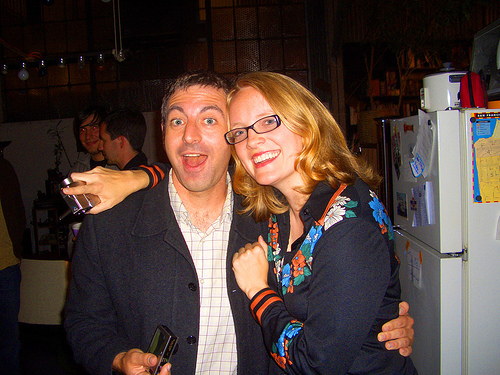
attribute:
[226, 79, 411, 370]
woman — middle age, posing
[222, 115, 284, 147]
glasses — black, on the wall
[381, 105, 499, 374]
fridge — white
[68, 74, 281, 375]
man — posing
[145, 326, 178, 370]
camera — silver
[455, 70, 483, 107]
bag — red, black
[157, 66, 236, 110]
hair — dark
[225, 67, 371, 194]
hair — light colored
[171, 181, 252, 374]
shirt — colorful, white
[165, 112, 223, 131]
eyes — bue, red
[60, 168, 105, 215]
camera — digital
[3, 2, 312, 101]
tiles — brown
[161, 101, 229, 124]
eye brows — arched